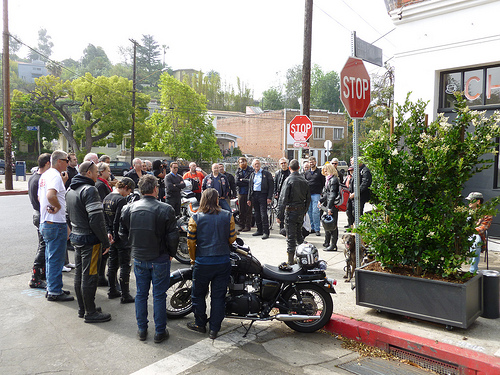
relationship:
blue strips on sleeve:
[183, 227, 198, 243] [181, 205, 243, 269]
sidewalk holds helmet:
[292, 235, 499, 370] [321, 213, 334, 229]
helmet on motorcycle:
[294, 241, 317, 270] [158, 239, 335, 333]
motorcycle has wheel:
[153, 233, 337, 332] [282, 282, 334, 333]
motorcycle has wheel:
[166, 244, 337, 338] [161, 272, 193, 321]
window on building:
[419, 66, 486, 87] [201, 101, 388, 206]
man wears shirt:
[32, 144, 78, 307] [34, 166, 69, 226]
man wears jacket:
[128, 176, 181, 340] [123, 199, 178, 261]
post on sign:
[296, 2, 327, 157] [275, 96, 325, 161]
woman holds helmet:
[316, 158, 346, 255] [317, 208, 337, 238]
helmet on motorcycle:
[293, 241, 316, 265] [164, 233, 334, 335]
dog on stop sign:
[344, 236, 359, 282] [337, 59, 370, 289]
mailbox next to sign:
[9, 157, 24, 179] [24, 120, 44, 133]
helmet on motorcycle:
[294, 241, 317, 270] [163, 237, 337, 342]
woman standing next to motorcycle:
[188, 187, 236, 333] [163, 239, 348, 349]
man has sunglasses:
[37, 149, 74, 301] [57, 154, 73, 168]